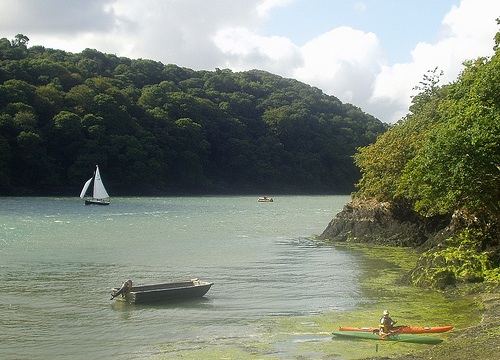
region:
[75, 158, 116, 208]
sail boat in the water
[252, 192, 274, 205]
small yellow raft in the water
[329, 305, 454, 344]
orange kayak in the water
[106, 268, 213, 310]
small motorboat in the water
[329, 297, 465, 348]
person in a kayak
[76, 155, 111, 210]
sail boat with white sail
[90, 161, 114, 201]
white sail on a sailboat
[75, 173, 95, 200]
white sail on a sailboat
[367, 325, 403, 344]
orange oar used for kayaking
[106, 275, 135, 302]
motor on a motorboat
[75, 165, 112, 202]
a boat with white sails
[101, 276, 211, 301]
a small boat with its motor out of the water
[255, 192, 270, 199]
a tiny boat in the distance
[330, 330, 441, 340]
a green boat on the shore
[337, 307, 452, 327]
an orange boat next to the green boat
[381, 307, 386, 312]
the white hat of the person in the orange boat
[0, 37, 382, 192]
the forested side of the left bank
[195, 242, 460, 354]
green stuff on top of the water on the right side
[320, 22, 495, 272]
rock and trees on the right bank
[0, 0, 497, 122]
sky with clouds above the water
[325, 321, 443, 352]
person in green kayak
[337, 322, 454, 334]
person in orange kayak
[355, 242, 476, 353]
green algae in water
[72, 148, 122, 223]
sailboat in water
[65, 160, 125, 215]
sailboat has white sail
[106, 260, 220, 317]
empty boat in water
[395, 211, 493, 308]
green algae on rocks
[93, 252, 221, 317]
boat propeller lifted up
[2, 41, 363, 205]
lush green trees in background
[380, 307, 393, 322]
person wearing tan hat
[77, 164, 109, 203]
a white sailboat in the distance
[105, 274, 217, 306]
an unmanned wooden boat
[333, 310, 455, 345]
a man in a kayak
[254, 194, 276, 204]
a wooden boat far in the distance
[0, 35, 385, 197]
a lush green forest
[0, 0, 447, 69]
a cloudy blue sky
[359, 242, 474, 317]
murky green water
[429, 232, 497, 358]
foliage on the coast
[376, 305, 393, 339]
a man in the kayak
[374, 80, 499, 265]
green and orange leaves on the coast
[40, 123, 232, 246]
a sailboat in the water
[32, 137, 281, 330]
a sailboat on a body of water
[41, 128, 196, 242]
a sailboat with white sail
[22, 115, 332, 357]
boats on the water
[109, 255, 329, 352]
a small green boat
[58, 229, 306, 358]
a small green boat on the water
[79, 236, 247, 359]
a small boat on the water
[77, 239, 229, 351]
a green boat in the water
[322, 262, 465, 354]
a person on a kayak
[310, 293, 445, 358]
a kayak in the water